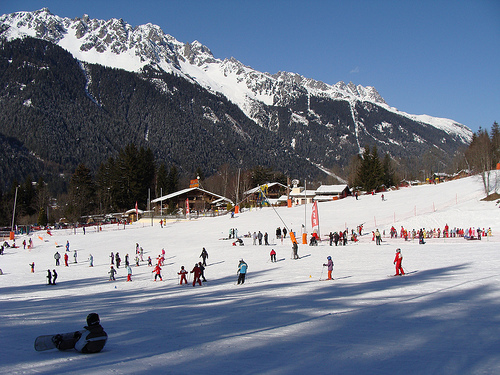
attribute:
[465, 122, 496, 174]
trees — dark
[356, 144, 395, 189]
trees — dark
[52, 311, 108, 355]
man — sitting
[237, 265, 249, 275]
jacket — light blue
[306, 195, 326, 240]
flag — red, white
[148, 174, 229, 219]
building — brown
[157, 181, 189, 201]
roof — red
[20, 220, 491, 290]
group —  of people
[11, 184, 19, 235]
pole — tall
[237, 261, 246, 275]
jacket — blue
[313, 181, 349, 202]
building — Brown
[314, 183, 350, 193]
roof —  covered with snow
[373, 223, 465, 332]
person —  sitting